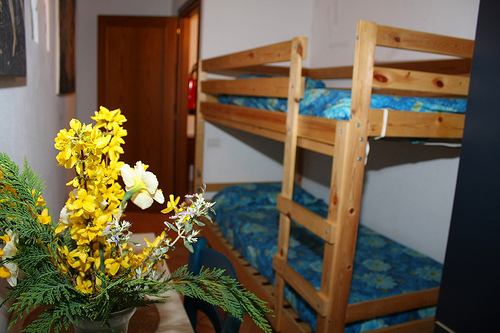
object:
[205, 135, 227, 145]
light switch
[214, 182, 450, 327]
sheets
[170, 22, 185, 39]
hinges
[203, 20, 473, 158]
bed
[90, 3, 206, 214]
doors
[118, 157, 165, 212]
rose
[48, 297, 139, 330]
flowerpot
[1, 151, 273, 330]
evergreens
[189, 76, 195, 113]
extinguisher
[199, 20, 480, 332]
bunkbeds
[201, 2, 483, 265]
wall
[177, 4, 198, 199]
doorway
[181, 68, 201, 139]
object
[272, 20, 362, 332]
ladder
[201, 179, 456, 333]
bed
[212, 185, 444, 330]
bedspread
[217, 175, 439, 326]
blue sheet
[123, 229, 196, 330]
table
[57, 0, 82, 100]
picture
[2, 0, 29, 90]
wood frame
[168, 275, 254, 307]
leaves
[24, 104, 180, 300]
flower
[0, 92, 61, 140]
white wall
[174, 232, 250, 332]
chair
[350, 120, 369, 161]
bolts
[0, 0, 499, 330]
bedroom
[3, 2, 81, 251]
wall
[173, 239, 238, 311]
ground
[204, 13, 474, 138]
top